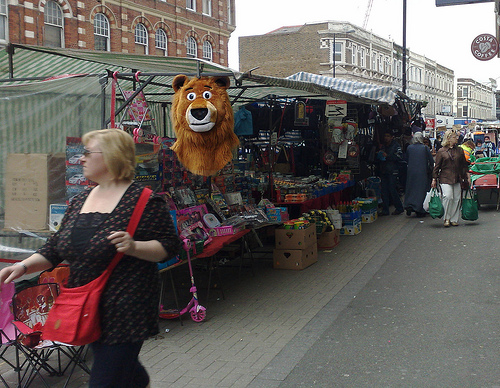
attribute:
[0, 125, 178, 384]
woman — deep large, large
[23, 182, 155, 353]
bag — red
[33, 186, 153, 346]
bag — red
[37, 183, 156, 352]
bag — red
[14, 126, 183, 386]
woman — large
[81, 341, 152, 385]
pants — black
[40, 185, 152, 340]
purse — red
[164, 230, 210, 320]
scooter — pink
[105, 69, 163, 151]
stroller — pink, white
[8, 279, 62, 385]
chair — red, white, black, child's, folding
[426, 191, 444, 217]
bag — green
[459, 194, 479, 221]
bag — green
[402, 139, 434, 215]
coat — blue, long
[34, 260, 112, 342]
handbag — red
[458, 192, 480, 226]
bag — green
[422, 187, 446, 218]
bag — green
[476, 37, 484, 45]
sign — hanging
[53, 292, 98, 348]
bag — red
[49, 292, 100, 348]
purse — red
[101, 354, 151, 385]
pants — dark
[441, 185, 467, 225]
pants — white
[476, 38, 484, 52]
sign — round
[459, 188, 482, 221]
bag — green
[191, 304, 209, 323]
wheel — pink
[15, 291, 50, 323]
folding chair — red